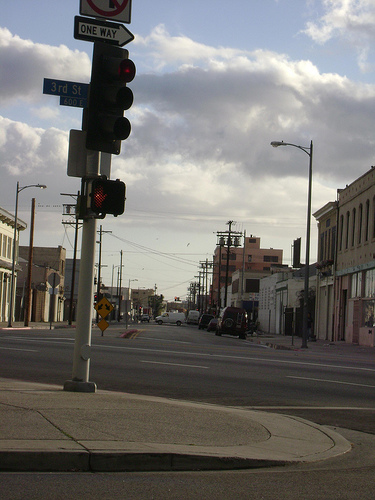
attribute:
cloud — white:
[1, 1, 373, 241]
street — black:
[237, 372, 275, 396]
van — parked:
[215, 304, 254, 346]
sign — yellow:
[93, 293, 114, 338]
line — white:
[140, 356, 208, 374]